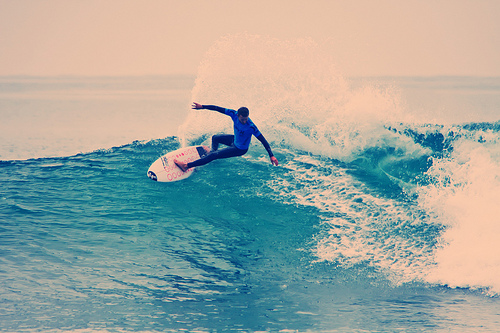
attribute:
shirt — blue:
[193, 98, 274, 158]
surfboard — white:
[149, 143, 213, 184]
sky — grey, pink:
[2, 6, 477, 101]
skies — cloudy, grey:
[1, 1, 498, 76]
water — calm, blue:
[0, 76, 498, 161]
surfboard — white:
[152, 143, 234, 207]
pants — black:
[181, 131, 248, 168]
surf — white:
[324, 82, 485, 275]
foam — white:
[269, 82, 499, 282]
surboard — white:
[129, 141, 222, 183]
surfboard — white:
[143, 144, 208, 181]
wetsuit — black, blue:
[209, 119, 296, 173]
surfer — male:
[128, 95, 282, 207]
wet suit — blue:
[178, 100, 269, 192]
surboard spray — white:
[136, 115, 221, 187]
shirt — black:
[223, 107, 259, 152]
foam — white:
[332, 165, 428, 281]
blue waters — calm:
[3, 73, 498, 159]